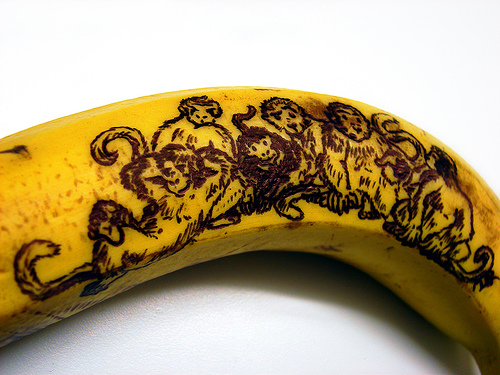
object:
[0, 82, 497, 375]
banana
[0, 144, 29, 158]
brown spots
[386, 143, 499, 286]
6 monkeys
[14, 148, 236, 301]
monkey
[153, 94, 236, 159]
monkey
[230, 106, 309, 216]
monkey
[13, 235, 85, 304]
tail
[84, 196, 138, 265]
crossed legs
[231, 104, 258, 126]
s shaped tail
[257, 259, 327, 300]
shadow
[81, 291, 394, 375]
plate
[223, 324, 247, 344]
light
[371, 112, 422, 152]
tail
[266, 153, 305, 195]
arms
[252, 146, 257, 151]
black dots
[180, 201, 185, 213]
black lines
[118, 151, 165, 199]
arm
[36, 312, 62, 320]
scratch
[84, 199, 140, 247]
leg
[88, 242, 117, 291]
leg